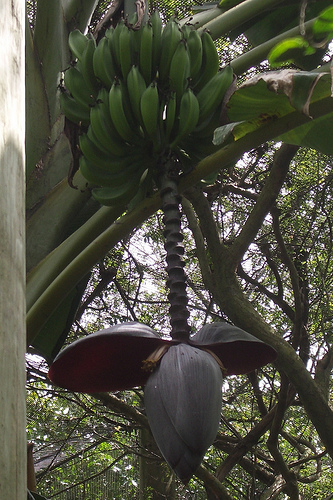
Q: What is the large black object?
A: A pod.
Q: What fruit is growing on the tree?
A: Bananas.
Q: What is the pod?
A: A large seed.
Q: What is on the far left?
A: Trunk of banana tree.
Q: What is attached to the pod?
A: Large dark petals.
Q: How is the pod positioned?
A: It is hanging down.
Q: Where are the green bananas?
A: On the tree.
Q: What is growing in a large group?
A: Bananas.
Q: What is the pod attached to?
A: The banana tree.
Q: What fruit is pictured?
A: Green bananas.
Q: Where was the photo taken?
A: In a forest.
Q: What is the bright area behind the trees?
A: The sky.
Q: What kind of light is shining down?
A: Sunlight.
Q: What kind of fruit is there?
A: Bananas.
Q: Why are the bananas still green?
A: They are not ripe.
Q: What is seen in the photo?
A: A banana tree.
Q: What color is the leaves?
A: Green.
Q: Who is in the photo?
A: Nobody.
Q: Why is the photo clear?
A: Its during the day.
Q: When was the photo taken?
A: Daytime.